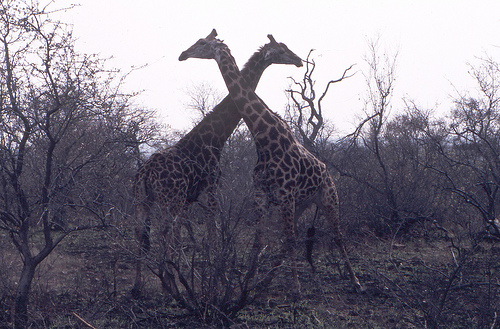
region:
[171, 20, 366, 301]
giraffe on the right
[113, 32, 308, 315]
giraffe on the left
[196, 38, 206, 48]
left eye of a giraffe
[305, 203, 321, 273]
tail of a giraffe on the right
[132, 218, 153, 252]
tail of the giraffe on the left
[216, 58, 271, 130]
neck of the giraffe on the right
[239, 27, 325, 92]
head of the giraffe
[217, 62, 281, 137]
neck of the giraffe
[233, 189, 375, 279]
legs of the giraffe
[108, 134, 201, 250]
back of the giraffe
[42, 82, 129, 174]
branches on the tree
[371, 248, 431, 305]
dirt under the animal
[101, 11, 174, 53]
sky above the land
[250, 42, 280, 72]
ear of the animal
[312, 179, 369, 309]
back leg of animal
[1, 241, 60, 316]
branch of a tree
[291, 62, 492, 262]
the trees are bare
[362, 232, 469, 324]
the twigs on the ground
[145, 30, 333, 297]
the giraffes are spotted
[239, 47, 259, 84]
the mane is short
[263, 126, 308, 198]
the spots are brown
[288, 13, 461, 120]
the sky is gray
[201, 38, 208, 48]
the eye is black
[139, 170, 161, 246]
the tail is long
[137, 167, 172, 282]
the tail is spotted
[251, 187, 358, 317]
the legs are skinny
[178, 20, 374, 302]
Giraffe in front with long neck.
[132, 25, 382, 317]
Giraffe in back with long neck.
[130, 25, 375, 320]
Giraffe in front with 2 small ears.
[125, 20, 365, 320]
Giraffe in back with 2 small ears.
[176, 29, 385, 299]
Giraffe in front with 4 legs.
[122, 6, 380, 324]
Giraffe in back with 2 small ears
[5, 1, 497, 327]
Dead tree's with no leaves.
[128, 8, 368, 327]
Giraffe in front with spots.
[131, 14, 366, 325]
Giraffe in back with spots.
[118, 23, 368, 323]
Giraffe with short tail.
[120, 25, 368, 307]
two giraffes twisting necks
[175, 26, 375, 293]
a giraffe walking by another giraffe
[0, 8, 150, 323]
a tree with no leaves on it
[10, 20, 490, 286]
a savannah with giraffes in it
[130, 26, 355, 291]
two giraffes embrace each other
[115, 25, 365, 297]
giraffes fighting each other by neck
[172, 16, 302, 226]
giraffes slamming their necks into each other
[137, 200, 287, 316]
a dead, dried out bush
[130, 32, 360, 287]
two large mammals in nature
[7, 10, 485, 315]
a wild forest with giraffes walking in it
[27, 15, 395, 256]
these are two giraffes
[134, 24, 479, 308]
the giraffes necks are crossed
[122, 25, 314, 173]
the giraffes are forming an X